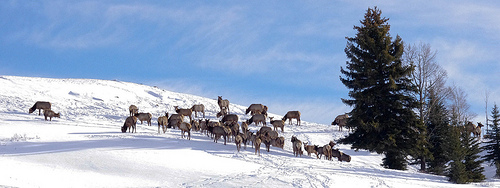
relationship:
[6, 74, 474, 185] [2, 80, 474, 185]
shadow on ground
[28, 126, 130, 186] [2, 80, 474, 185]
snow is in ground on ground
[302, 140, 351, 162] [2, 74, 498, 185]
animals on snow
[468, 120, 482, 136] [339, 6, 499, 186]
moose in trees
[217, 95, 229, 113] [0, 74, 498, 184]
moose on slope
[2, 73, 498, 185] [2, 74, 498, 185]
tracks in snow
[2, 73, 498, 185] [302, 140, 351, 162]
tracks from animals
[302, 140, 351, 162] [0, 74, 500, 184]
animals on hill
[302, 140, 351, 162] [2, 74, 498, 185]
animals in snow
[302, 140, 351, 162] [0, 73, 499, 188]
animals on hill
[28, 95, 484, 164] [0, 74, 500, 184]
caribou on hill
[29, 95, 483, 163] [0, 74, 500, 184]
reindeer on hillside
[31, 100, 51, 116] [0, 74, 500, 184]
reindeer on hillside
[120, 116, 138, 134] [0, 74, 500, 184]
reindeer on hillside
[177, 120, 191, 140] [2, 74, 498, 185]
animal in snow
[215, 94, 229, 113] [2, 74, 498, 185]
animal in snow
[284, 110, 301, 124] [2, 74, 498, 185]
animal in snow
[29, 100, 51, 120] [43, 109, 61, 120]
animal near animal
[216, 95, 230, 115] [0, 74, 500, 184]
antelope standing on hill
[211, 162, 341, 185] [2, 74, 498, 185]
hoof prints in snow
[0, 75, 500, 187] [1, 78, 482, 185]
snow on land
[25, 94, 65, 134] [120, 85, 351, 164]
animals are away from herd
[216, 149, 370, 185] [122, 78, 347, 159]
tacks are behind animals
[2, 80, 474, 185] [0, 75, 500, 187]
ground covered with snow